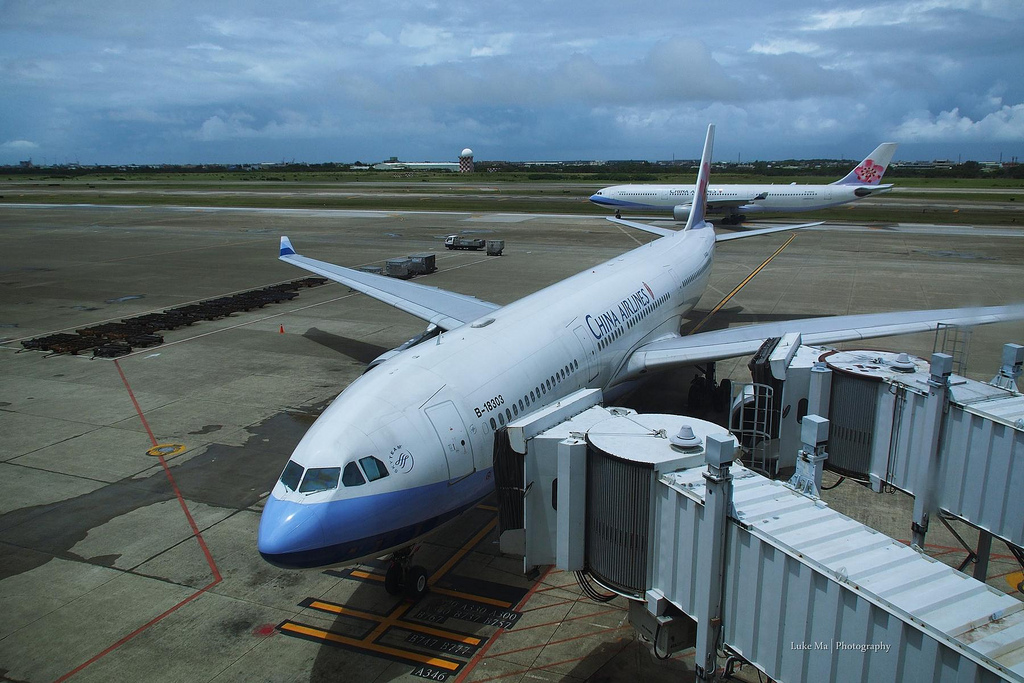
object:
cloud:
[208, 16, 328, 69]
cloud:
[739, 28, 822, 70]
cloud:
[912, 101, 1011, 158]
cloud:
[391, 19, 459, 78]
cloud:
[370, 19, 502, 74]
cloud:
[890, 95, 1016, 152]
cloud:
[198, 111, 333, 155]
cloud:
[5, 119, 44, 160]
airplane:
[255, 124, 1022, 570]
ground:
[0, 170, 1024, 683]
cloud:
[748, 28, 833, 77]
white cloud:
[808, 4, 910, 44]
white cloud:
[421, 28, 519, 74]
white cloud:
[893, 97, 1024, 144]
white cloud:
[191, 110, 374, 142]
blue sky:
[0, 0, 1024, 165]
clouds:
[175, 106, 495, 147]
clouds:
[250, 39, 378, 86]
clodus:
[451, 33, 875, 119]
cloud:
[76, 18, 534, 127]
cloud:
[375, 61, 621, 131]